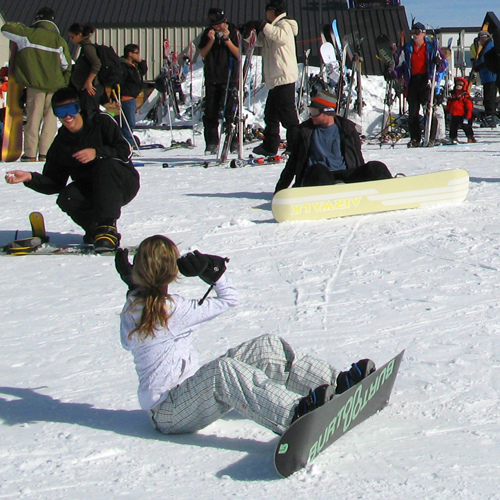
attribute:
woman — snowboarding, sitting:
[114, 235, 406, 477]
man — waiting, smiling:
[9, 89, 141, 254]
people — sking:
[6, 3, 500, 475]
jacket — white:
[2, 18, 74, 92]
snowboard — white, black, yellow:
[274, 349, 405, 476]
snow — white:
[0, 56, 497, 500]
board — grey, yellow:
[274, 352, 405, 475]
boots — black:
[92, 227, 122, 253]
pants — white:
[153, 335, 340, 435]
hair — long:
[130, 235, 181, 335]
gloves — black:
[176, 251, 226, 284]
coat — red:
[450, 79, 475, 119]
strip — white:
[5, 28, 69, 68]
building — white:
[2, 1, 415, 128]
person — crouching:
[6, 89, 140, 249]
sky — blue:
[405, 3, 500, 33]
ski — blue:
[332, 19, 343, 53]